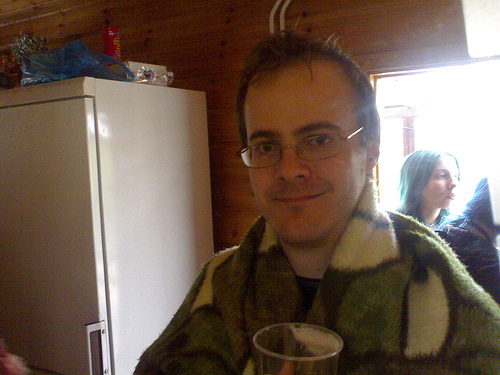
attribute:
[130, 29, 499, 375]
man — white, smiling, happy, young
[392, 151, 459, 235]
woman — young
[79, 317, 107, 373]
handle — metal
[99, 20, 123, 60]
goods — red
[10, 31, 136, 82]
bag — blue, plastic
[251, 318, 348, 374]
mug — plastic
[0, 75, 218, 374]
refrigerator — white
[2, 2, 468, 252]
wall — wood, brown, wooden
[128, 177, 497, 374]
blanket — green